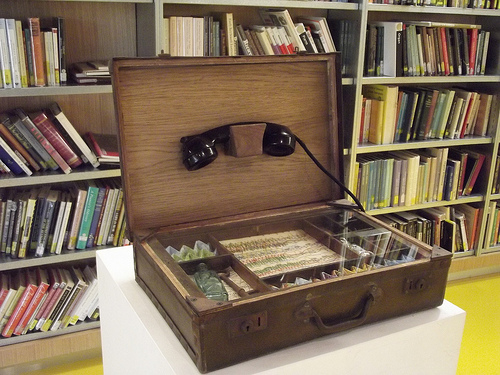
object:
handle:
[299, 289, 380, 334]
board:
[114, 54, 342, 235]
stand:
[94, 244, 471, 373]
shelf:
[363, 73, 499, 90]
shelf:
[354, 137, 494, 156]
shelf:
[369, 195, 483, 217]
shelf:
[1, 170, 114, 187]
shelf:
[2, 245, 105, 270]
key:
[215, 270, 251, 298]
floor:
[444, 273, 499, 374]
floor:
[36, 353, 103, 374]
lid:
[110, 53, 343, 233]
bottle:
[194, 261, 229, 303]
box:
[108, 56, 449, 375]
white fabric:
[172, 239, 218, 257]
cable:
[292, 134, 370, 214]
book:
[364, 84, 401, 144]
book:
[394, 90, 405, 143]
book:
[405, 90, 419, 142]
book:
[415, 85, 434, 142]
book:
[430, 85, 455, 139]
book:
[50, 14, 67, 85]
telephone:
[178, 118, 364, 210]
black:
[183, 139, 217, 167]